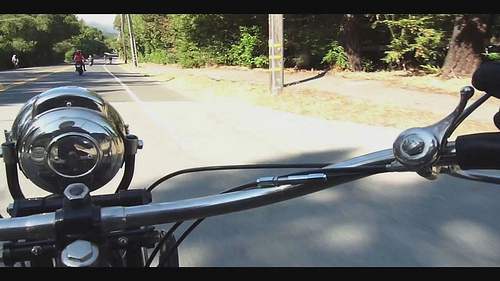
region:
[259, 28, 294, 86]
yellow lines on the pole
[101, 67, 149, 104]
white line along the road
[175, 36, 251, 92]
sidewalk beside the road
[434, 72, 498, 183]
handle on the motorcycle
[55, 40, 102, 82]
motorcyclist in front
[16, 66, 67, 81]
yellow line down the center of road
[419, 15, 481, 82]
large tree next to sidewalk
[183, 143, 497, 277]
shadow on the road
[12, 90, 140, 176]
back of headlight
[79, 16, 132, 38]
sky above the trees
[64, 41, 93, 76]
motorbike on the road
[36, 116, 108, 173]
reflection in the silver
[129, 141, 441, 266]
black wires running down the handlebar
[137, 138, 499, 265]
shadow on the ground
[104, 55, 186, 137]
white line painted on the side of the road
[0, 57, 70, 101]
yellow line in the middle of the road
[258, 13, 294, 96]
wooden post by the road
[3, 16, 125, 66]
thick green trees lining the road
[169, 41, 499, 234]
silver and black handlebar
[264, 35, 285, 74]
three yellow marks on the post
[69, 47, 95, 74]
People riding motorcycles down the road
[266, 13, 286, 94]
a telephone poll on the side of the road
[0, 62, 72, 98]
A double yellow line painted in the middle of the road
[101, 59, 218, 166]
a white line painted on the side of the road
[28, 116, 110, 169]
A reflection of the motorcyclist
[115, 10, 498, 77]
a bunch of trees on the side of the road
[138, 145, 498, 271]
a large shadow from the trees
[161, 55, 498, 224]
a handlebar of the motorcycle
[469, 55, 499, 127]
the man's hand on the handlebar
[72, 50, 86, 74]
a woman on the back of the motorcycle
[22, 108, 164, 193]
mirror on front of bike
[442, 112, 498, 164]
black handle of bike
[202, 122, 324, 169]
road is light grey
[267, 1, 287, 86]
brown pole on grass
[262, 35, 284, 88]
yellow lines on pole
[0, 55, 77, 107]
yellow line on road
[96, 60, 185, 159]
white line on road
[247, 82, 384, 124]
green grass near road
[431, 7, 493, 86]
large brown thick trunk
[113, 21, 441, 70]
green trees beside road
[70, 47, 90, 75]
Person wearing pink on a motorcylce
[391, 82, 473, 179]
Silver chrome handle bar brake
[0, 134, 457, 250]
Silver chrome handle bar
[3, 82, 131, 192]
Silver chrome head light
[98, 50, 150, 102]
White strip on street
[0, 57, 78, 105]
Yellow line on streeet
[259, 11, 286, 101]
Brown and white pole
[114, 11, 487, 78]
Green Trees on the side of the road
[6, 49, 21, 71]
Person on the street wearing white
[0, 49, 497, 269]
Long grey road